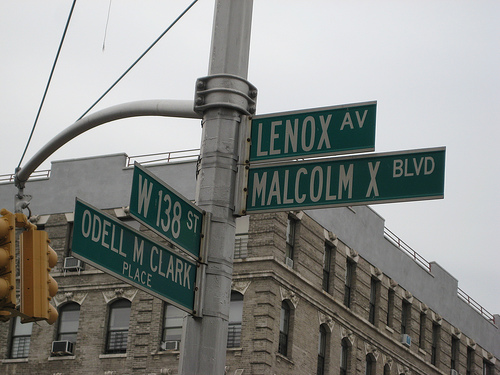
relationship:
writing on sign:
[249, 164, 376, 200] [243, 152, 448, 209]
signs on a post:
[242, 112, 447, 220] [176, 0, 259, 375]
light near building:
[1, 216, 53, 318] [0, 146, 500, 375]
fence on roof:
[0, 147, 217, 183] [0, 144, 499, 309]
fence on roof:
[379, 215, 497, 328] [0, 144, 499, 309]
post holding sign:
[199, 1, 301, 373] [254, 111, 373, 153]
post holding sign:
[199, 1, 301, 373] [245, 148, 450, 207]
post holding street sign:
[199, 1, 301, 373] [126, 160, 206, 261]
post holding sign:
[199, 1, 301, 373] [70, 224, 207, 325]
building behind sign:
[247, 255, 418, 373] [248, 97, 377, 161]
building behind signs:
[247, 255, 418, 373] [242, 146, 446, 210]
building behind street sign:
[247, 255, 418, 373] [128, 160, 205, 252]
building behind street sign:
[247, 255, 418, 373] [71, 242, 195, 309]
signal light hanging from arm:
[1, 197, 80, 354] [6, 98, 193, 186]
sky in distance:
[0, 1, 498, 311] [345, 53, 444, 102]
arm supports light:
[6, 98, 193, 186] [4, 197, 67, 329]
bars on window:
[101, 328, 131, 353] [102, 292, 134, 358]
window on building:
[3, 304, 33, 360] [1, 148, 499, 372]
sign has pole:
[248, 97, 377, 161] [175, 0, 257, 374]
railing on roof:
[384, 219, 484, 313] [372, 223, 494, 298]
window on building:
[104, 292, 134, 355] [68, 83, 498, 370]